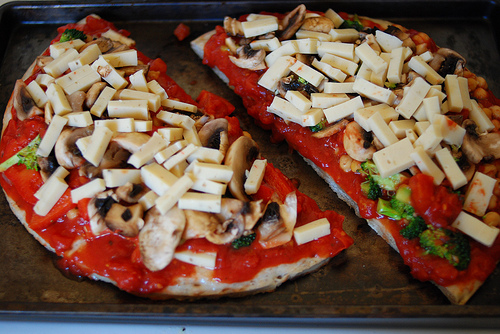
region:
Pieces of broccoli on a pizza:
[359, 169, 476, 270]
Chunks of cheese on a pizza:
[68, 69, 181, 159]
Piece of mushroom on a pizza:
[258, 204, 289, 246]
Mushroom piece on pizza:
[343, 121, 380, 163]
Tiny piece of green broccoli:
[17, 140, 42, 172]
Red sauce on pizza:
[222, 244, 281, 284]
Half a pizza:
[191, 7, 498, 306]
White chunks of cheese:
[132, 165, 210, 213]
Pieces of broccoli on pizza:
[382, 184, 458, 251]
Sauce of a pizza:
[60, 215, 129, 282]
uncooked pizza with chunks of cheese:
[10, 17, 489, 299]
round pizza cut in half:
[7, 0, 497, 305]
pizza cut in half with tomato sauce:
[1, 3, 498, 320]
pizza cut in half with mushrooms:
[1, 0, 495, 316]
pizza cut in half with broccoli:
[13, 0, 497, 301]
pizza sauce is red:
[0, 12, 497, 299]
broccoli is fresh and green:
[11, 70, 473, 275]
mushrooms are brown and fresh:
[25, 1, 488, 272]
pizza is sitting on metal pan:
[0, 0, 495, 320]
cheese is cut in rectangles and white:
[13, 0, 498, 270]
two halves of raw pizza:
[29, 13, 491, 293]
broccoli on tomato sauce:
[375, 186, 459, 257]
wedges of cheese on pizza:
[124, 153, 210, 184]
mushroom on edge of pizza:
[222, 137, 267, 194]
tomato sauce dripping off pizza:
[44, 237, 128, 281]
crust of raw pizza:
[171, 258, 322, 298]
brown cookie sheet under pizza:
[300, 279, 400, 322]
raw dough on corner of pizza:
[187, 25, 221, 65]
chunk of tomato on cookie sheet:
[169, 19, 199, 43]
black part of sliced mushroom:
[246, 139, 264, 174]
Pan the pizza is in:
[10, 273, 70, 305]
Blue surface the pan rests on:
[0, 321, 90, 327]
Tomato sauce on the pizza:
[65, 238, 132, 275]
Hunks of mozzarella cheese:
[38, 164, 62, 215]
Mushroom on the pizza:
[86, 188, 145, 238]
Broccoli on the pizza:
[413, 223, 473, 270]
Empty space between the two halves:
[173, 50, 205, 89]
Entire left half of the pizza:
[5, 21, 347, 308]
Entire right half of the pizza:
[193, 12, 498, 309]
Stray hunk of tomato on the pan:
[165, 18, 193, 49]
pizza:
[43, 21, 494, 253]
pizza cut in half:
[15, 8, 445, 312]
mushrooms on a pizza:
[191, 124, 326, 294]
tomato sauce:
[6, 141, 206, 327]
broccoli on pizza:
[353, 182, 468, 281]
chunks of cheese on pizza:
[62, 65, 184, 190]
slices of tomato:
[416, 168, 482, 243]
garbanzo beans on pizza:
[471, 76, 498, 120]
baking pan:
[13, 4, 389, 309]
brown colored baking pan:
[9, 6, 317, 313]